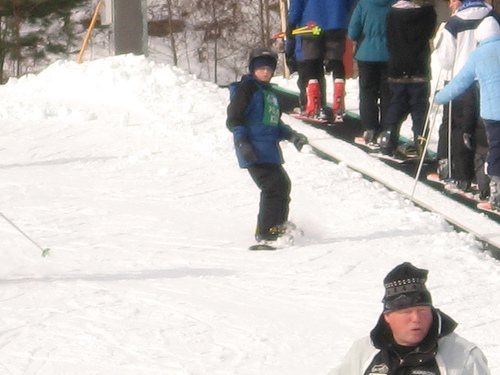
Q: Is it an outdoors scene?
A: Yes, it is outdoors.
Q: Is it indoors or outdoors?
A: It is outdoors.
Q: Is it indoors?
A: No, it is outdoors.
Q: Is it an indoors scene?
A: No, it is outdoors.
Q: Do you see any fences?
A: No, there are no fences.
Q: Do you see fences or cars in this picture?
A: No, there are no fences or cars.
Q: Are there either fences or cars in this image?
A: No, there are no fences or cars.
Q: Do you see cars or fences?
A: No, there are no fences or cars.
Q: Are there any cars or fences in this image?
A: No, there are no fences or cars.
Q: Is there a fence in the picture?
A: No, there are no fences.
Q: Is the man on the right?
A: Yes, the man is on the right of the image.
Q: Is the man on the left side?
A: No, the man is on the right of the image.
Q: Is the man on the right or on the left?
A: The man is on the right of the image.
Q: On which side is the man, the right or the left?
A: The man is on the right of the image.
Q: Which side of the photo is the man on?
A: The man is on the right of the image.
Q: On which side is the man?
A: The man is on the right of the image.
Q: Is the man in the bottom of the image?
A: Yes, the man is in the bottom of the image.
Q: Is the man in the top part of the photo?
A: No, the man is in the bottom of the image.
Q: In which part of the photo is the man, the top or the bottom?
A: The man is in the bottom of the image.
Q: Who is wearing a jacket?
A: The man is wearing a jacket.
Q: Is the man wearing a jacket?
A: Yes, the man is wearing a jacket.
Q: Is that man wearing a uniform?
A: No, the man is wearing a jacket.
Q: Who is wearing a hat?
A: The man is wearing a hat.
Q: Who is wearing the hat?
A: The man is wearing a hat.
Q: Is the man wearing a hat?
A: Yes, the man is wearing a hat.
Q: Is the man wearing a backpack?
A: No, the man is wearing a hat.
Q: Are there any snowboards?
A: Yes, there is a snowboard.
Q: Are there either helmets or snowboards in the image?
A: Yes, there is a snowboard.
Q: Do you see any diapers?
A: No, there are no diapers.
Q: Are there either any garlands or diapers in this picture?
A: No, there are no diapers or garlands.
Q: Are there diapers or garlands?
A: No, there are no diapers or garlands.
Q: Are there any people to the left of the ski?
A: No, the person is to the right of the ski.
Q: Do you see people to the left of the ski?
A: No, the person is to the right of the ski.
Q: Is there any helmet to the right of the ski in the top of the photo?
A: No, there is a person to the right of the ski.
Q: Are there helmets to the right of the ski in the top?
A: No, there is a person to the right of the ski.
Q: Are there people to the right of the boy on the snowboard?
A: Yes, there is a person to the right of the boy.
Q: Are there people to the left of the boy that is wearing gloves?
A: No, the person is to the right of the boy.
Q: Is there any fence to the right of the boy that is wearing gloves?
A: No, there is a person to the right of the boy.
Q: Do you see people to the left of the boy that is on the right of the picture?
A: Yes, there is a person to the left of the boy.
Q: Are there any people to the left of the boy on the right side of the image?
A: Yes, there is a person to the left of the boy.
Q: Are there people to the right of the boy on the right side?
A: No, the person is to the left of the boy.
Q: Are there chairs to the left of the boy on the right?
A: No, there is a person to the left of the boy.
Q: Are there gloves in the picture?
A: Yes, there are gloves.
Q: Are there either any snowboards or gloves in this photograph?
A: Yes, there are gloves.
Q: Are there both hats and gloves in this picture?
A: Yes, there are both gloves and a hat.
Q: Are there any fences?
A: No, there are no fences.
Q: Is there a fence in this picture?
A: No, there are no fences.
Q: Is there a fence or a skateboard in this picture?
A: No, there are no fences or skateboards.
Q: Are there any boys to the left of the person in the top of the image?
A: Yes, there is a boy to the left of the person.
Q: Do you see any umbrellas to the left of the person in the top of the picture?
A: No, there is a boy to the left of the person.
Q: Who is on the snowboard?
A: The boy is on the snowboard.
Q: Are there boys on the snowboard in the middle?
A: Yes, there is a boy on the snow board.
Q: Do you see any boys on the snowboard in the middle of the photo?
A: Yes, there is a boy on the snow board.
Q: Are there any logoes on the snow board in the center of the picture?
A: No, there is a boy on the snowboard.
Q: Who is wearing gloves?
A: The boy is wearing gloves.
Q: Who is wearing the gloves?
A: The boy is wearing gloves.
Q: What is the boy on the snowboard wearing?
A: The boy is wearing gloves.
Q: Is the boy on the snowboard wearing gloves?
A: Yes, the boy is wearing gloves.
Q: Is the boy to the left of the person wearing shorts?
A: No, the boy is wearing gloves.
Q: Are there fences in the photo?
A: No, there are no fences.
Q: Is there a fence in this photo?
A: No, there are no fences.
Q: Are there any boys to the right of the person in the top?
A: Yes, there is a boy to the right of the person.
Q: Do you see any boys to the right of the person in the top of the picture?
A: Yes, there is a boy to the right of the person.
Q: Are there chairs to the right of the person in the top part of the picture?
A: No, there is a boy to the right of the person.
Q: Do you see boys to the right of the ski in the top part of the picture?
A: Yes, there is a boy to the right of the ski.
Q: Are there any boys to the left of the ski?
A: No, the boy is to the right of the ski.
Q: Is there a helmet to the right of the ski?
A: No, there is a boy to the right of the ski.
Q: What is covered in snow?
A: The hill is covered in snow.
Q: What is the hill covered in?
A: The hill is covered in snow.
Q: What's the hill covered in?
A: The hill is covered in snow.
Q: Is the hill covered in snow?
A: Yes, the hill is covered in snow.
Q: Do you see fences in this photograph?
A: No, there are no fences.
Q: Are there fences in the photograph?
A: No, there are no fences.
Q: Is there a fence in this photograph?
A: No, there are no fences.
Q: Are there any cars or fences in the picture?
A: No, there are no fences or cars.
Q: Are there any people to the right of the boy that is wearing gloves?
A: Yes, there is a person to the right of the boy.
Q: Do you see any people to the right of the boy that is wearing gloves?
A: Yes, there is a person to the right of the boy.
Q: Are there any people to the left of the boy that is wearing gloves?
A: No, the person is to the right of the boy.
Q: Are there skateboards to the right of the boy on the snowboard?
A: No, there is a person to the right of the boy.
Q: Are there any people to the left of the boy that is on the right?
A: Yes, there is a person to the left of the boy.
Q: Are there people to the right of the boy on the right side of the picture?
A: No, the person is to the left of the boy.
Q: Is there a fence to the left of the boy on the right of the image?
A: No, there is a person to the left of the boy.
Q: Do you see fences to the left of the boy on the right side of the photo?
A: No, there is a person to the left of the boy.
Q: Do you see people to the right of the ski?
A: Yes, there is a person to the right of the ski.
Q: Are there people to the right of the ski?
A: Yes, there is a person to the right of the ski.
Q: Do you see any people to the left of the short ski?
A: No, the person is to the right of the ski.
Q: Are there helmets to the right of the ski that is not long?
A: No, there is a person to the right of the ski.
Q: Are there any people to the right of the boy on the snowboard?
A: Yes, there is a person to the right of the boy.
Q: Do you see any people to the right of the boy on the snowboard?
A: Yes, there is a person to the right of the boy.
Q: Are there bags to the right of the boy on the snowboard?
A: No, there is a person to the right of the boy.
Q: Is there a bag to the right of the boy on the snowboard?
A: No, there is a person to the right of the boy.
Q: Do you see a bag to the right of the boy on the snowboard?
A: No, there is a person to the right of the boy.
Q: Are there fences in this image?
A: No, there are no fences.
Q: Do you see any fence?
A: No, there are no fences.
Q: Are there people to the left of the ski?
A: No, the person is to the right of the ski.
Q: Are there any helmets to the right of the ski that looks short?
A: No, there is a person to the right of the ski.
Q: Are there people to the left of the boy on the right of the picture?
A: Yes, there is a person to the left of the boy.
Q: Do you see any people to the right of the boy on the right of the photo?
A: No, the person is to the left of the boy.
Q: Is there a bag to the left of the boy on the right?
A: No, there is a person to the left of the boy.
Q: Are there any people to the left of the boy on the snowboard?
A: No, the person is to the right of the boy.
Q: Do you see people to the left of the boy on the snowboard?
A: No, the person is to the right of the boy.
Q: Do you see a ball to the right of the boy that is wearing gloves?
A: No, there is a person to the right of the boy.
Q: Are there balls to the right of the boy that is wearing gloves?
A: No, there is a person to the right of the boy.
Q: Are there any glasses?
A: No, there are no glasses.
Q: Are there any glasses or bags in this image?
A: No, there are no glasses or bags.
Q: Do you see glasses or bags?
A: No, there are no glasses or bags.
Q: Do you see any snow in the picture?
A: Yes, there is snow.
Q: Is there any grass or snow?
A: Yes, there is snow.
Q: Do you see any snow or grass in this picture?
A: Yes, there is snow.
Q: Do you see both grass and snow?
A: No, there is snow but no grass.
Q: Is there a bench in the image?
A: No, there are no benches.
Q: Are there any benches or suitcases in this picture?
A: No, there are no benches or suitcases.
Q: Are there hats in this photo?
A: Yes, there is a hat.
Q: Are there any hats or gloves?
A: Yes, there is a hat.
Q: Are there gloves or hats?
A: Yes, there is a hat.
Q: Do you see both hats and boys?
A: Yes, there are both a hat and a boy.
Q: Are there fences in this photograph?
A: No, there are no fences.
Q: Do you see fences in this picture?
A: No, there are no fences.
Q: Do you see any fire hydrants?
A: No, there are no fire hydrants.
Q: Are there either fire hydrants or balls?
A: No, there are no fire hydrants or balls.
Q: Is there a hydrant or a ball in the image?
A: No, there are no fire hydrants or balls.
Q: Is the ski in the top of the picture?
A: Yes, the ski is in the top of the image.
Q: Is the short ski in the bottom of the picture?
A: No, the ski is in the top of the image.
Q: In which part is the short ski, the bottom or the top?
A: The ski is in the top of the image.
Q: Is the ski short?
A: Yes, the ski is short.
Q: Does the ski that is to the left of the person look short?
A: Yes, the ski is short.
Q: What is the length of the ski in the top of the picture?
A: The ski is short.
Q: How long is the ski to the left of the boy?
A: The ski is short.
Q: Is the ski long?
A: No, the ski is short.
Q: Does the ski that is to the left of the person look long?
A: No, the ski is short.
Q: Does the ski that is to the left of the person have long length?
A: No, the ski is short.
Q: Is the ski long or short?
A: The ski is short.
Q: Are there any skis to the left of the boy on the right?
A: Yes, there is a ski to the left of the boy.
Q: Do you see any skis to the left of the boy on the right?
A: Yes, there is a ski to the left of the boy.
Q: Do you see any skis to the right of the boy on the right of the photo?
A: No, the ski is to the left of the boy.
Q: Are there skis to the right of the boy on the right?
A: No, the ski is to the left of the boy.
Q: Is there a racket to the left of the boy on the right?
A: No, there is a ski to the left of the boy.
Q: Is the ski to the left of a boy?
A: Yes, the ski is to the left of a boy.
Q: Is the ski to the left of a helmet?
A: No, the ski is to the left of a boy.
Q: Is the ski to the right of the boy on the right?
A: No, the ski is to the left of the boy.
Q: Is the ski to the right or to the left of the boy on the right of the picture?
A: The ski is to the left of the boy.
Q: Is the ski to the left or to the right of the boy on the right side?
A: The ski is to the left of the boy.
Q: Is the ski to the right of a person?
A: No, the ski is to the left of a person.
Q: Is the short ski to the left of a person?
A: Yes, the ski is to the left of a person.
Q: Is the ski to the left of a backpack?
A: No, the ski is to the left of a person.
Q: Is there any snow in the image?
A: Yes, there is snow.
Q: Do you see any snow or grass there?
A: Yes, there is snow.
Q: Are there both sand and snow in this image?
A: No, there is snow but no sand.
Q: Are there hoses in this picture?
A: No, there are no hoses.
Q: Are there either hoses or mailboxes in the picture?
A: No, there are no hoses or mailboxes.